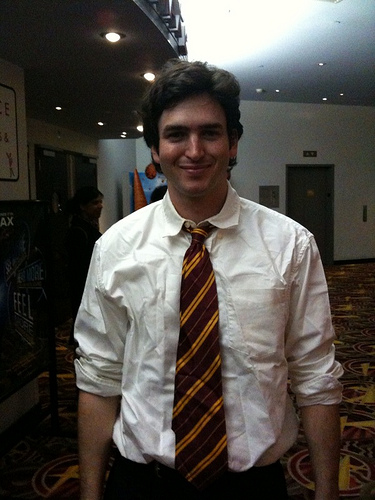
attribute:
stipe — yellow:
[189, 223, 206, 243]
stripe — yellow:
[168, 272, 219, 331]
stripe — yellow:
[180, 289, 222, 355]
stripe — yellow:
[172, 364, 218, 418]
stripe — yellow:
[170, 398, 204, 447]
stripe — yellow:
[168, 432, 249, 483]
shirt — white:
[88, 208, 330, 469]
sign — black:
[298, 143, 321, 161]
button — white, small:
[185, 220, 192, 230]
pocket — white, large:
[236, 287, 286, 365]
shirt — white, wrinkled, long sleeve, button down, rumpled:
[74, 190, 339, 467]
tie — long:
[168, 222, 231, 485]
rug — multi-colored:
[9, 259, 373, 498]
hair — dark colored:
[132, 59, 245, 153]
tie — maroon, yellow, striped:
[174, 226, 229, 488]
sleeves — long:
[70, 280, 338, 412]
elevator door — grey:
[285, 163, 340, 264]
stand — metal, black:
[3, 197, 61, 424]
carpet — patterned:
[23, 257, 373, 495]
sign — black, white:
[1, 83, 20, 181]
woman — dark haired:
[68, 183, 117, 332]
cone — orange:
[132, 165, 153, 212]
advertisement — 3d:
[125, 171, 180, 215]